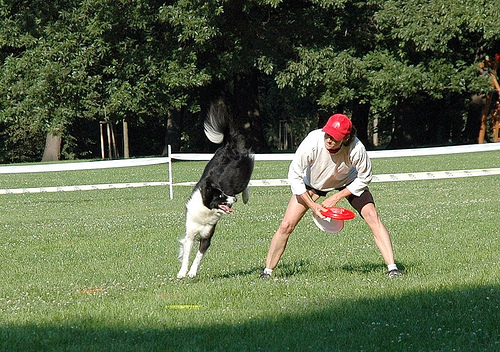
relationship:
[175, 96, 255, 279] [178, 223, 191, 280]
dog has leg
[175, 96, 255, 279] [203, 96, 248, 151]
dog has tail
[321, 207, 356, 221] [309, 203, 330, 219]
frisbee in hand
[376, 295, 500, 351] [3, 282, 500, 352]
flower in shade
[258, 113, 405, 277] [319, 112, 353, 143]
person has cap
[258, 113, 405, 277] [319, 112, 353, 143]
person wearing cap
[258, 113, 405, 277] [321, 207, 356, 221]
person holding frisbee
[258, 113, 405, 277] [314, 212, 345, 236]
person holding frisbee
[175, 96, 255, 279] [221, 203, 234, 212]
dog has tongue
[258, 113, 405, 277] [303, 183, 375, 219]
person wearing shorts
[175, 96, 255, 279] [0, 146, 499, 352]
dog on grass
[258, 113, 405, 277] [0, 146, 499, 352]
person on grass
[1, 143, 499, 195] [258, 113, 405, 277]
fence behind person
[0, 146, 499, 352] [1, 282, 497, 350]
grass has shadow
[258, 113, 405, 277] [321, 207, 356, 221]
person playing frisbee